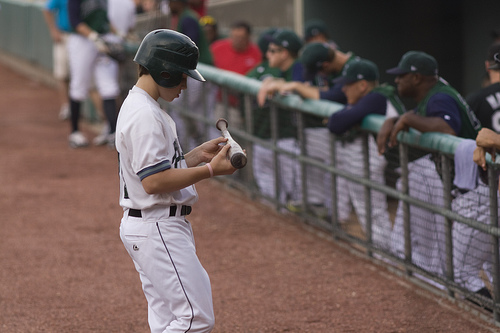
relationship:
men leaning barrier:
[288, 18, 493, 187] [223, 52, 496, 314]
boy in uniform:
[110, 29, 243, 333] [46, 94, 291, 246]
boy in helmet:
[110, 29, 243, 333] [124, 23, 246, 81]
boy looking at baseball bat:
[110, 18, 255, 330] [209, 115, 254, 173]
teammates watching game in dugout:
[228, 25, 498, 275] [100, 9, 498, 280]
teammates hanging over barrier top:
[228, 25, 498, 275] [96, 34, 500, 162]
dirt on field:
[191, 197, 386, 317] [5, 23, 467, 330]